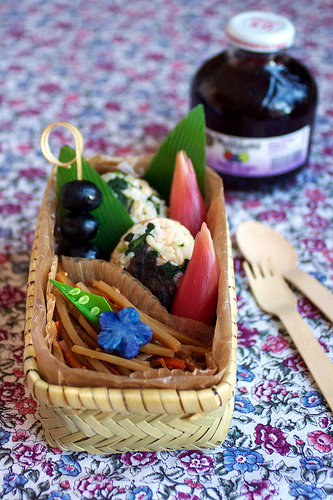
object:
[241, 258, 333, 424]
fork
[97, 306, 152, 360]
flower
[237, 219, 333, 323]
spoon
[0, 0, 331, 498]
table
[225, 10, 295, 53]
lid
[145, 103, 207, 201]
green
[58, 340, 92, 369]
sticks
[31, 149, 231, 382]
wax paper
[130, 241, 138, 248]
green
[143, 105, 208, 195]
leaf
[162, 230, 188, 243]
rice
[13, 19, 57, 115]
flowered pattern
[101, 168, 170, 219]
ball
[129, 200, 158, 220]
flower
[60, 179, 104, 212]
olive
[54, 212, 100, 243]
olive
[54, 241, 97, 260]
olive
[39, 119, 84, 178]
stick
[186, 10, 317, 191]
bottle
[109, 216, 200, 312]
ball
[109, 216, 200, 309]
sea weed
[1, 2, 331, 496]
tablecloth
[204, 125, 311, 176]
label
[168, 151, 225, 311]
vegetables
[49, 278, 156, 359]
vegetable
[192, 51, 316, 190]
drink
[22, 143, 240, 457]
basket